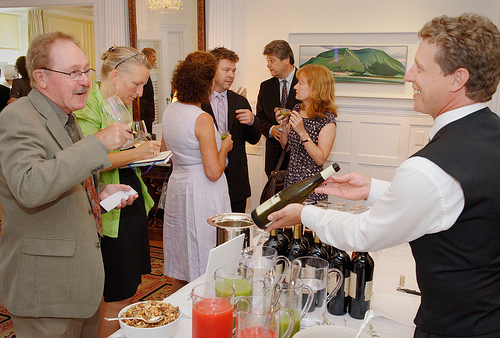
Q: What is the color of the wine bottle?
A: Green.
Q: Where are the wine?
A: On the table.